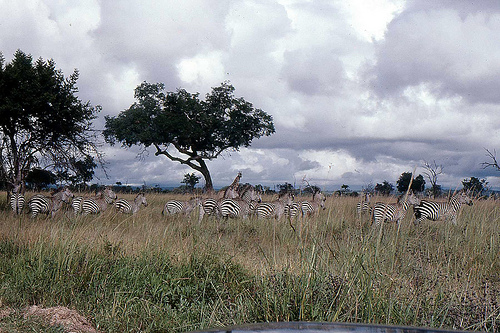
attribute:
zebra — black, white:
[289, 180, 316, 226]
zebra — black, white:
[370, 195, 408, 224]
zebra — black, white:
[83, 189, 105, 211]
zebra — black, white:
[116, 192, 148, 217]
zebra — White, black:
[354, 186, 428, 238]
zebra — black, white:
[239, 192, 303, 228]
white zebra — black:
[113, 190, 147, 217]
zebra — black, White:
[215, 183, 262, 230]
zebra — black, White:
[199, 184, 240, 221]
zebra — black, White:
[251, 189, 293, 221]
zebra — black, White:
[284, 185, 327, 220]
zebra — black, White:
[110, 192, 149, 217]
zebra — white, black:
[259, 184, 289, 221]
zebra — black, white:
[406, 189, 485, 240]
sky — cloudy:
[291, 16, 473, 126]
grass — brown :
[0, 210, 494, 325]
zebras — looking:
[212, 175, 477, 226]